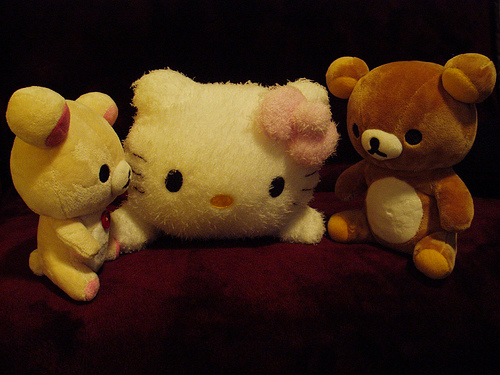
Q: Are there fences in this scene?
A: No, there are no fences.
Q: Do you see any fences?
A: No, there are no fences.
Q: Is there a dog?
A: No, there are no dogs.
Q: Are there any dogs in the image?
A: No, there are no dogs.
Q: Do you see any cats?
A: Yes, there is a cat.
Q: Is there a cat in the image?
A: Yes, there is a cat.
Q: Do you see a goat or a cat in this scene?
A: Yes, there is a cat.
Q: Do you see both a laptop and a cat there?
A: No, there is a cat but no laptops.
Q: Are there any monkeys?
A: No, there are no monkeys.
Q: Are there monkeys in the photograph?
A: No, there are no monkeys.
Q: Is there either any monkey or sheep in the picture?
A: No, there are no monkeys or sheep.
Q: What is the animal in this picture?
A: The animal is a cat.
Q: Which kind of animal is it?
A: The animal is a cat.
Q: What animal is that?
A: This is a cat.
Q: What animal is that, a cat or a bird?
A: This is a cat.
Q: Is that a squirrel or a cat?
A: That is a cat.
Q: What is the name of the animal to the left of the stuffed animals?
A: The animal is a cat.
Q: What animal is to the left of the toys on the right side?
A: The animal is a cat.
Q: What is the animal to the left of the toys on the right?
A: The animal is a cat.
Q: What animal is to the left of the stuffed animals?
A: The animal is a cat.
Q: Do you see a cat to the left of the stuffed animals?
A: Yes, there is a cat to the left of the stuffed animals.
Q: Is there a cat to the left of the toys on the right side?
A: Yes, there is a cat to the left of the stuffed animals.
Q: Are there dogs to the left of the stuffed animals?
A: No, there is a cat to the left of the stuffed animals.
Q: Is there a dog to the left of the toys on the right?
A: No, there is a cat to the left of the stuffed animals.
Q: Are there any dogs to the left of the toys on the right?
A: No, there is a cat to the left of the stuffed animals.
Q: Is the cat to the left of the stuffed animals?
A: Yes, the cat is to the left of the stuffed animals.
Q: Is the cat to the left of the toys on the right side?
A: Yes, the cat is to the left of the stuffed animals.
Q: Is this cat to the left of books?
A: No, the cat is to the left of the stuffed animals.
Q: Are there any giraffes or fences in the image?
A: No, there are no fences or giraffes.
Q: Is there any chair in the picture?
A: Yes, there is a chair.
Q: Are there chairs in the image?
A: Yes, there is a chair.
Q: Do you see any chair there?
A: Yes, there is a chair.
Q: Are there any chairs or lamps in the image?
A: Yes, there is a chair.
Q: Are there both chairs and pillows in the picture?
A: No, there is a chair but no pillows.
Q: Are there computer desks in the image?
A: No, there are no computer desks.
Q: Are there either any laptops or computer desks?
A: No, there are no computer desks or laptops.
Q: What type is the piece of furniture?
A: The piece of furniture is a chair.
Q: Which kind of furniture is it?
A: The piece of furniture is a chair.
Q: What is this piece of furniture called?
A: This is a chair.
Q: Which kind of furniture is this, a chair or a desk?
A: This is a chair.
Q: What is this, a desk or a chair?
A: This is a chair.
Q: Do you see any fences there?
A: No, there are no fences.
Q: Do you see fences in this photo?
A: No, there are no fences.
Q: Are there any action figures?
A: No, there are no action figures.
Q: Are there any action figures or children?
A: No, there are no action figures or children.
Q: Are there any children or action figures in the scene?
A: No, there are no action figures or children.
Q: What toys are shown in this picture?
A: The toys are stuffed animals.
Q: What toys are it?
A: The toys are stuffed animals.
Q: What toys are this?
A: Those are stuffed animals.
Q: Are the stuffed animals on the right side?
A: Yes, the stuffed animals are on the right of the image.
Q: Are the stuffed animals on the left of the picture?
A: No, the stuffed animals are on the right of the image.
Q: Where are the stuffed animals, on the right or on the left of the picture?
A: The stuffed animals are on the right of the image.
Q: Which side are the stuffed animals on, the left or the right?
A: The stuffed animals are on the right of the image.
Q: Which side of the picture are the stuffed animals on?
A: The stuffed animals are on the right of the image.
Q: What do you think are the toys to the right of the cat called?
A: The toys are stuffed animals.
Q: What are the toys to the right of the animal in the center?
A: The toys are stuffed animals.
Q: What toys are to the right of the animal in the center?
A: The toys are stuffed animals.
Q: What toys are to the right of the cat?
A: The toys are stuffed animals.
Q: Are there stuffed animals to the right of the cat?
A: Yes, there are stuffed animals to the right of the cat.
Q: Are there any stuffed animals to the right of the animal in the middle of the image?
A: Yes, there are stuffed animals to the right of the cat.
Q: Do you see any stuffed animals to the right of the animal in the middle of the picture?
A: Yes, there are stuffed animals to the right of the cat.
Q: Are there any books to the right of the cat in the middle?
A: No, there are stuffed animals to the right of the cat.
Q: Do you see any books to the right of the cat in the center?
A: No, there are stuffed animals to the right of the cat.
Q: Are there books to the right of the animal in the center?
A: No, there are stuffed animals to the right of the cat.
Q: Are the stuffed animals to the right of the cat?
A: Yes, the stuffed animals are to the right of the cat.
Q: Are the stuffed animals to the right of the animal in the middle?
A: Yes, the stuffed animals are to the right of the cat.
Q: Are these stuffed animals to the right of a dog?
A: No, the stuffed animals are to the right of the cat.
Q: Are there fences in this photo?
A: No, there are no fences.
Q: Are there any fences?
A: No, there are no fences.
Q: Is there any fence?
A: No, there are no fences.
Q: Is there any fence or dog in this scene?
A: No, there are no fences or dogs.